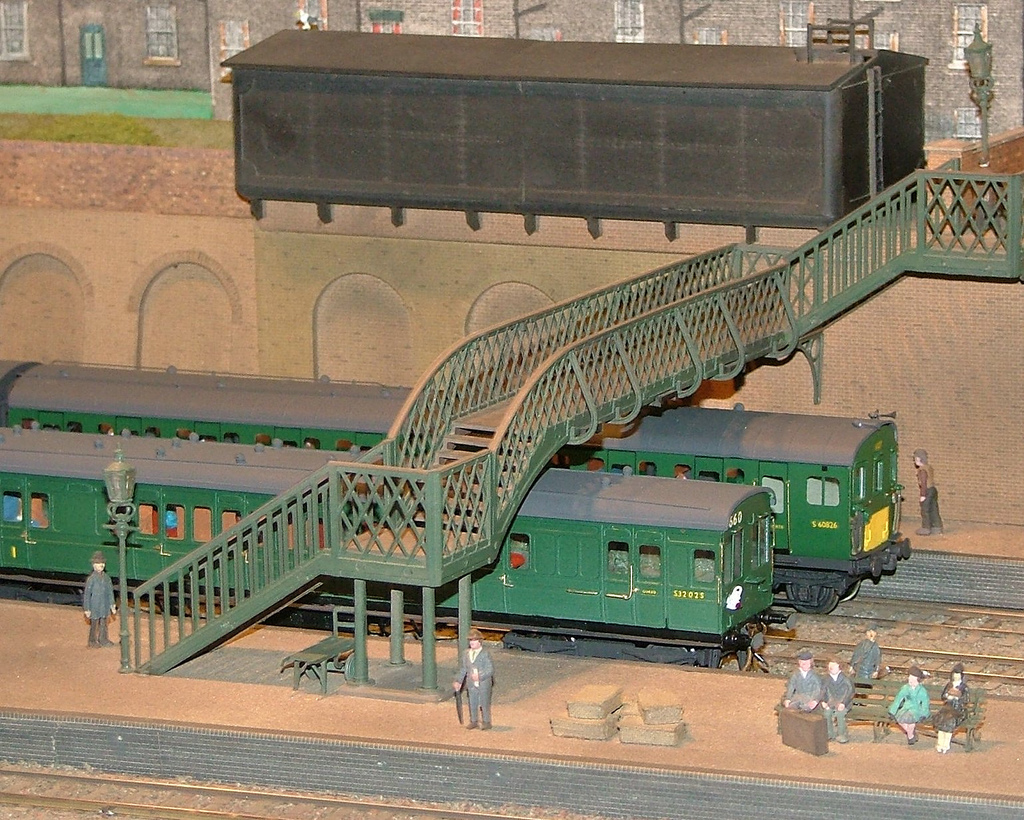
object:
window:
[448, 0, 484, 38]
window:
[142, 0, 181, 64]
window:
[218, 15, 253, 81]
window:
[782, 0, 817, 48]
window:
[948, 6, 990, 77]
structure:
[220, 24, 933, 248]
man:
[82, 550, 118, 648]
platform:
[0, 598, 391, 743]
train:
[0, 348, 914, 615]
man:
[450, 628, 497, 731]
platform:
[500, 660, 768, 775]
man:
[782, 650, 826, 713]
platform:
[827, 741, 1024, 780]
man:
[848, 622, 882, 682]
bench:
[276, 635, 364, 694]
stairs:
[124, 442, 480, 672]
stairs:
[411, 418, 514, 534]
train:
[5, 425, 780, 668]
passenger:
[887, 665, 933, 746]